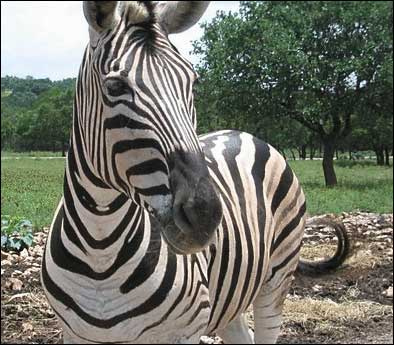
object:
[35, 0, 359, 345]
zebra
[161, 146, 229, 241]
nose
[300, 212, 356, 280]
tail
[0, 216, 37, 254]
plant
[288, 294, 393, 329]
patches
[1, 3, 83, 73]
sky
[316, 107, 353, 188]
trunk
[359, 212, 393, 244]
rocks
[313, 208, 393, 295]
dirt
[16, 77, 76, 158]
plant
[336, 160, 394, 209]
grass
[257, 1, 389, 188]
plant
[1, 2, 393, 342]
camera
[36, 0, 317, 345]
animal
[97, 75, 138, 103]
eye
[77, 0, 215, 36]
ears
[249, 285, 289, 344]
left leg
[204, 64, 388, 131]
background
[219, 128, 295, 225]
strip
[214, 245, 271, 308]
strip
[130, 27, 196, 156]
strip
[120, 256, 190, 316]
strip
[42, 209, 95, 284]
strip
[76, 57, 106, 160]
black strip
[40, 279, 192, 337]
black strip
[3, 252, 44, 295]
rocks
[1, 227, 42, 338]
dirt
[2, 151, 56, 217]
field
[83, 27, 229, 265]
curious face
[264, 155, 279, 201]
grey stripes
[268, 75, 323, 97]
branches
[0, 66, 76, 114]
hill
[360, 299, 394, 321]
grass